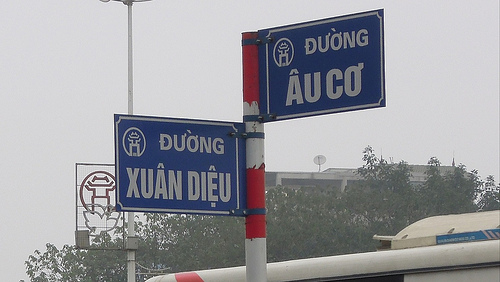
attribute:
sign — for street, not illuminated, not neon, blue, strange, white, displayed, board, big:
[115, 114, 247, 216]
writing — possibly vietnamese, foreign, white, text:
[127, 131, 233, 204]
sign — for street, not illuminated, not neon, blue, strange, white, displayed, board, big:
[261, 9, 386, 123]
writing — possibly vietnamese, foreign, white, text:
[284, 27, 368, 107]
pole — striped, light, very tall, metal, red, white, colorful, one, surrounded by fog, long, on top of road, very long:
[242, 34, 268, 279]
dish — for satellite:
[313, 153, 329, 173]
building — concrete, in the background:
[268, 165, 475, 230]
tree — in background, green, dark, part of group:
[364, 148, 497, 250]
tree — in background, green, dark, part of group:
[267, 179, 383, 262]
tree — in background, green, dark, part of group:
[143, 213, 246, 279]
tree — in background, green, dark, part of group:
[19, 212, 127, 278]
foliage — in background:
[22, 145, 497, 279]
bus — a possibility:
[371, 210, 498, 278]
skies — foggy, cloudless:
[5, 5, 496, 279]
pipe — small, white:
[148, 239, 497, 280]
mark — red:
[176, 270, 203, 279]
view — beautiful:
[5, 3, 494, 275]